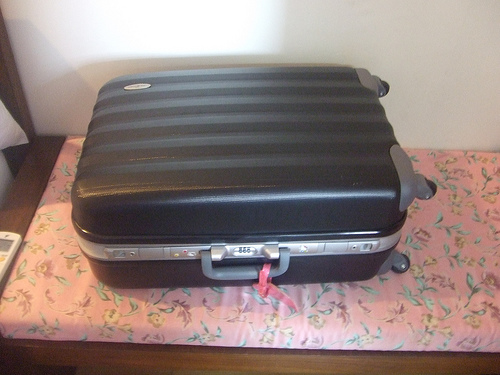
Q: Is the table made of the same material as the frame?
A: Yes, both the table and the frame are made of wood.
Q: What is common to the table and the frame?
A: The material, both the table and the frame are wooden.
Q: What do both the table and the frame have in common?
A: The material, both the table and the frame are wooden.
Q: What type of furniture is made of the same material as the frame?
A: The table is made of the same material as the frame.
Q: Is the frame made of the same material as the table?
A: Yes, both the frame and the table are made of wood.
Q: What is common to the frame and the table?
A: The material, both the frame and the table are wooden.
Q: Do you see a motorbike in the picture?
A: No, there are no motorcycles.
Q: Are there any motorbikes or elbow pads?
A: No, there are no motorbikes or elbow pads.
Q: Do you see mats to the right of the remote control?
A: Yes, there is a mat to the right of the remote control.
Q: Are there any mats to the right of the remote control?
A: Yes, there is a mat to the right of the remote control.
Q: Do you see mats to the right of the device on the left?
A: Yes, there is a mat to the right of the remote control.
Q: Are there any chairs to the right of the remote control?
A: No, there is a mat to the right of the remote control.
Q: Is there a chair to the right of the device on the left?
A: No, there is a mat to the right of the remote control.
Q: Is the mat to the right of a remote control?
A: Yes, the mat is to the right of a remote control.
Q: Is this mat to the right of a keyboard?
A: No, the mat is to the right of a remote control.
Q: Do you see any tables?
A: Yes, there is a table.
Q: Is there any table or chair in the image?
A: Yes, there is a table.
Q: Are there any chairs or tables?
A: Yes, there is a table.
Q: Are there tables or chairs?
A: Yes, there is a table.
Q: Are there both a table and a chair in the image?
A: No, there is a table but no chairs.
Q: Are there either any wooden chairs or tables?
A: Yes, there is a wood table.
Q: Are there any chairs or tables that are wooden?
A: Yes, the table is wooden.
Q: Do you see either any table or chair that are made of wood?
A: Yes, the table is made of wood.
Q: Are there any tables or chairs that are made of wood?
A: Yes, the table is made of wood.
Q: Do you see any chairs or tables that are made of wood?
A: Yes, the table is made of wood.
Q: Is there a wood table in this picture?
A: Yes, there is a wood table.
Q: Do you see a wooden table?
A: Yes, there is a wood table.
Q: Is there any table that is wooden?
A: Yes, there is a table that is wooden.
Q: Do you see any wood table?
A: Yes, there is a table that is made of wood.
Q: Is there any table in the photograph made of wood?
A: Yes, there is a table that is made of wood.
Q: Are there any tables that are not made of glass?
A: Yes, there is a table that is made of wood.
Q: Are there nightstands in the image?
A: No, there are no nightstands.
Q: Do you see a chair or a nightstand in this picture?
A: No, there are no nightstands or chairs.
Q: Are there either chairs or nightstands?
A: No, there are no nightstands or chairs.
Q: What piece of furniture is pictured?
A: The piece of furniture is a table.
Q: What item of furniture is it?
A: The piece of furniture is a table.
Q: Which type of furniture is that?
A: This is a table.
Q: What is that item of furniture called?
A: This is a table.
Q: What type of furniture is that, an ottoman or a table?
A: This is a table.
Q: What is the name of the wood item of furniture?
A: The piece of furniture is a table.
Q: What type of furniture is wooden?
A: The furniture is a table.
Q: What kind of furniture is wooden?
A: The furniture is a table.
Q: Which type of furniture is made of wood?
A: The furniture is a table.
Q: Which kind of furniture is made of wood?
A: The furniture is a table.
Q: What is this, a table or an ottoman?
A: This is a table.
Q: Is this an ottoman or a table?
A: This is a table.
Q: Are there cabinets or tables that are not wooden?
A: No, there is a table but it is wooden.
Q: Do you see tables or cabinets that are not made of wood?
A: No, there is a table but it is made of wood.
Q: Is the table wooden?
A: Yes, the table is wooden.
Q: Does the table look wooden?
A: Yes, the table is wooden.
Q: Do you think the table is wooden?
A: Yes, the table is wooden.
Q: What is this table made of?
A: The table is made of wood.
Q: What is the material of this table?
A: The table is made of wood.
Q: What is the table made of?
A: The table is made of wood.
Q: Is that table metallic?
A: No, the table is wooden.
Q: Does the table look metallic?
A: No, the table is wooden.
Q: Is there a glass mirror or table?
A: No, there is a table but it is wooden.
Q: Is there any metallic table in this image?
A: No, there is a table but it is wooden.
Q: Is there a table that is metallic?
A: No, there is a table but it is wooden.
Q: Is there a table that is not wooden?
A: No, there is a table but it is wooden.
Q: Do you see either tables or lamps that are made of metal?
A: No, there is a table but it is made of wood.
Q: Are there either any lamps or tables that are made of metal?
A: No, there is a table but it is made of wood.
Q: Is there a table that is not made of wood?
A: No, there is a table but it is made of wood.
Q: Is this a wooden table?
A: Yes, this is a wooden table.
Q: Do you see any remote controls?
A: Yes, there is a remote control.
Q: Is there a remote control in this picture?
A: Yes, there is a remote control.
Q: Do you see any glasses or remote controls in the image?
A: Yes, there is a remote control.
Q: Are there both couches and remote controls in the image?
A: No, there is a remote control but no couches.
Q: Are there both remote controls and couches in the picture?
A: No, there is a remote control but no couches.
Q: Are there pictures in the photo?
A: No, there are no pictures.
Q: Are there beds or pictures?
A: No, there are no pictures or beds.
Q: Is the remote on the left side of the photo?
A: Yes, the remote is on the left of the image.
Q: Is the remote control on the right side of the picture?
A: No, the remote control is on the left of the image.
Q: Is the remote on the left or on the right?
A: The remote is on the left of the image.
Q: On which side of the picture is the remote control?
A: The remote control is on the left of the image.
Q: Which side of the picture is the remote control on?
A: The remote control is on the left of the image.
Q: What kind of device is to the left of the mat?
A: The device is a remote control.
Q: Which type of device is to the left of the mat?
A: The device is a remote control.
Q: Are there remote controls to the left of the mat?
A: Yes, there is a remote control to the left of the mat.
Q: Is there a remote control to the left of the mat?
A: Yes, there is a remote control to the left of the mat.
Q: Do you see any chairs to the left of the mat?
A: No, there is a remote control to the left of the mat.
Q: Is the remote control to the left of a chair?
A: No, the remote control is to the left of the mat.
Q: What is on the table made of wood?
A: The remote is on the table.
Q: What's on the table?
A: The remote is on the table.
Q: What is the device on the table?
A: The device is a remote control.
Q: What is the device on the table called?
A: The device is a remote control.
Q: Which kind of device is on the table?
A: The device is a remote control.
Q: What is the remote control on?
A: The remote control is on the table.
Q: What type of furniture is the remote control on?
A: The remote control is on the table.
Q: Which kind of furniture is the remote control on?
A: The remote control is on the table.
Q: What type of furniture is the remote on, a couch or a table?
A: The remote is on a table.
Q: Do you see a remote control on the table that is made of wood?
A: Yes, there is a remote control on the table.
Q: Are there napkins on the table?
A: No, there is a remote control on the table.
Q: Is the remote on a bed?
A: No, the remote is on the table.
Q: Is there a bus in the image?
A: No, there are no buses.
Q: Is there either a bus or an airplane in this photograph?
A: No, there are no buses or airplanes.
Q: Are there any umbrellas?
A: No, there are no umbrellas.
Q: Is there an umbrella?
A: No, there are no umbrellas.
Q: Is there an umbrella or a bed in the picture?
A: No, there are no umbrellas or beds.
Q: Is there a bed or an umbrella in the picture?
A: No, there are no umbrellas or beds.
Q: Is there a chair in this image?
A: No, there are no chairs.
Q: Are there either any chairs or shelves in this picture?
A: No, there are no chairs or shelves.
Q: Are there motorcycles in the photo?
A: No, there are no motorcycles.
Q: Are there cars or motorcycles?
A: No, there are no motorcycles or cars.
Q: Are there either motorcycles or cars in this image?
A: No, there are no motorcycles or cars.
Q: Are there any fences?
A: No, there are no fences.